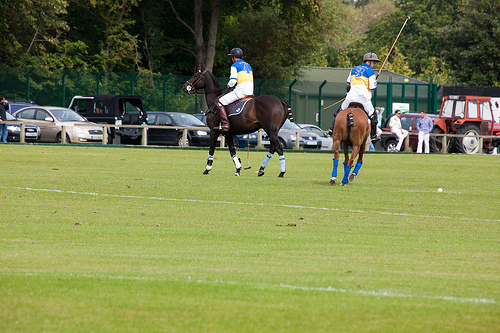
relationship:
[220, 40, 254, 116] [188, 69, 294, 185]
rider on horse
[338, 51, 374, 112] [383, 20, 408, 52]
man holding pole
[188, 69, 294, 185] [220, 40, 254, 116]
horse under rider